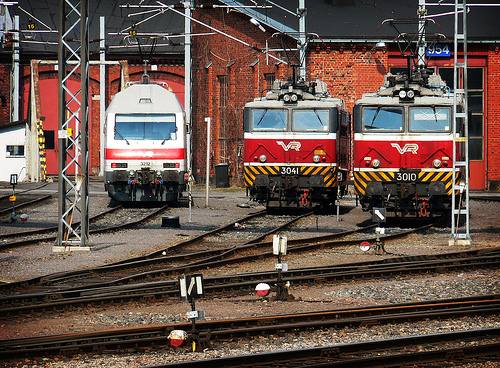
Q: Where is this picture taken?
A: A train station.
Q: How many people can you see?
A: 0.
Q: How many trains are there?
A: 3.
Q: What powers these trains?
A: Electricity.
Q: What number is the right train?
A: 3010.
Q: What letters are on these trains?
A: Vr.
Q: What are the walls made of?
A: Brick.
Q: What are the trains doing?
A: Parked.